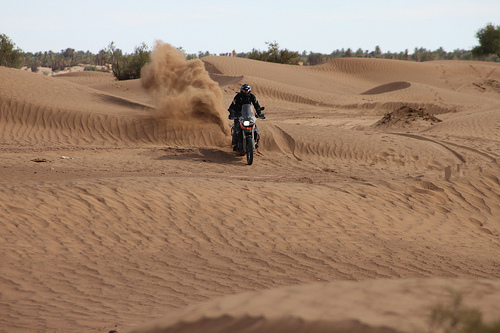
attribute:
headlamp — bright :
[239, 113, 252, 128]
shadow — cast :
[146, 130, 243, 170]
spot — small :
[356, 68, 410, 100]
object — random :
[50, 143, 81, 170]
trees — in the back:
[248, 42, 321, 62]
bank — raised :
[18, 100, 178, 160]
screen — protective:
[241, 105, 255, 115]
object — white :
[61, 154, 74, 162]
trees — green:
[30, 33, 168, 89]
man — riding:
[219, 76, 268, 121]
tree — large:
[468, 14, 498, 61]